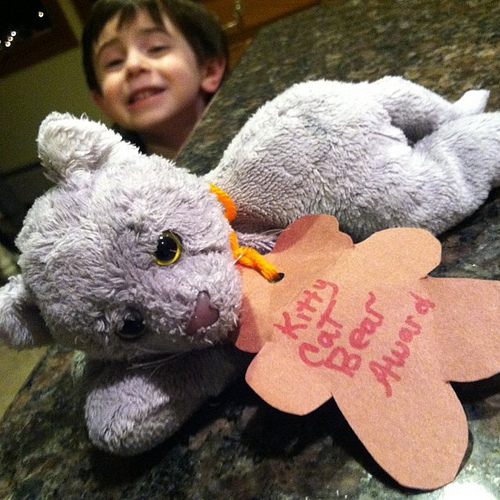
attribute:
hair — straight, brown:
[79, 3, 230, 103]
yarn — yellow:
[211, 184, 282, 286]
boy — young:
[66, 3, 240, 145]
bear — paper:
[17, 79, 494, 436]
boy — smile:
[80, 23, 262, 142]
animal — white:
[18, 87, 470, 346]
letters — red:
[270, 270, 446, 406]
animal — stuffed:
[0, 48, 492, 456]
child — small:
[78, 0, 235, 142]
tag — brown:
[229, 211, 498, 495]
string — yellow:
[203, 180, 279, 285]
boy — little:
[79, 1, 227, 129]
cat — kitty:
[4, 41, 497, 461]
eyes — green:
[96, 216, 186, 344]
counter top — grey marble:
[1, 324, 491, 498]